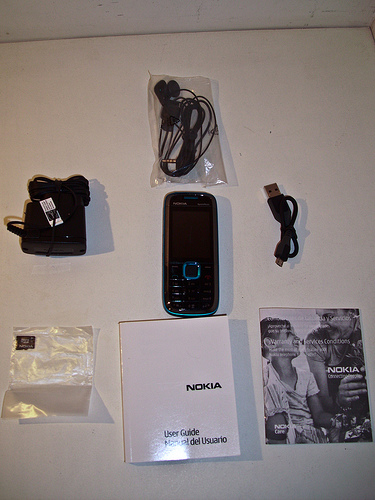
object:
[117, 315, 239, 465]
user guide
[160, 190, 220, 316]
phone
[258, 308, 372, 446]
warranty book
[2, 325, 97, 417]
bag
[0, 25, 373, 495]
table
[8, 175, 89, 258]
charger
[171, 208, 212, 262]
screen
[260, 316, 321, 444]
person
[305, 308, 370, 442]
person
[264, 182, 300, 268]
connector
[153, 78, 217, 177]
earphones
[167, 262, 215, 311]
keypad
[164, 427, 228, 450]
writing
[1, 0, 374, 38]
wall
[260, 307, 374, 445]
picture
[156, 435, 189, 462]
light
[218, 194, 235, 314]
shadow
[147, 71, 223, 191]
bag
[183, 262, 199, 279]
button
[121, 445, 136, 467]
corner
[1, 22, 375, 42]
edge